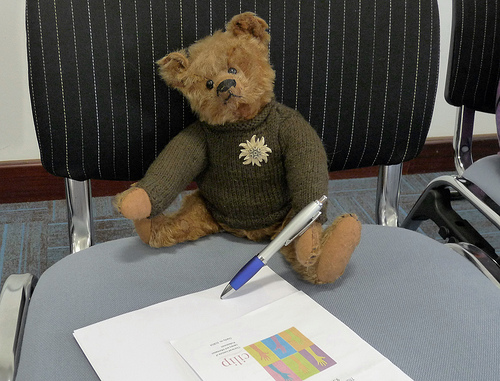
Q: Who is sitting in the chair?
A: A teddy bear.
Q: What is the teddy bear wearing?
A: A sweater.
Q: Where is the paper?
A: On the chair.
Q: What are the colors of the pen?
A: Blue and silver.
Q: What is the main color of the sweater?
A: Brown.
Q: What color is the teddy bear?
A: Brown.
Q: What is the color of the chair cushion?
A: Grey.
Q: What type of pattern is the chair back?
A: Stripes.